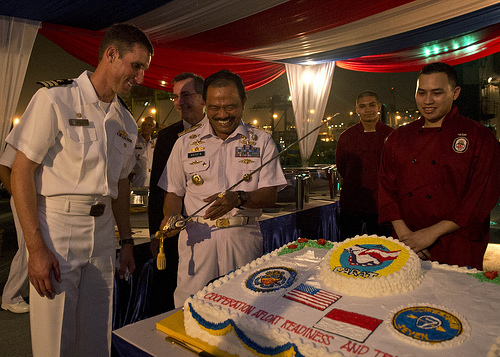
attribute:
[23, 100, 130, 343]
unifrom — white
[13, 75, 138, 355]
dress whites — white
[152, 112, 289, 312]
uniform — white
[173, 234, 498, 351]
cake — huge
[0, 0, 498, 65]
fabric — red and white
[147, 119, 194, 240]
suit — black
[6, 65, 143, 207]
shirt — white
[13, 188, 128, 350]
pants — white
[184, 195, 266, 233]
belt buckle — golden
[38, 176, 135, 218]
belt — white 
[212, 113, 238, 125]
mustache — black